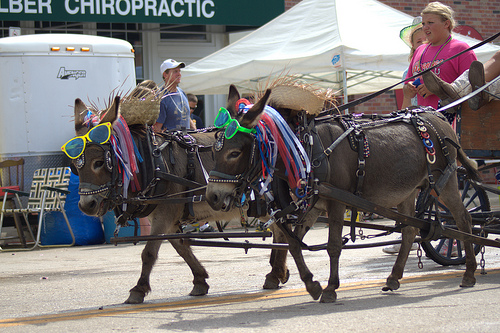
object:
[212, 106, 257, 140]
sunglasses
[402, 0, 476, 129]
woman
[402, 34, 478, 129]
shirt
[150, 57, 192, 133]
man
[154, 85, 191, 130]
shirt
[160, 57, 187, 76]
hat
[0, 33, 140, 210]
trailer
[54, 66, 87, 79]
logo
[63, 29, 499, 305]
cart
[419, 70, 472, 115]
boots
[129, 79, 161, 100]
donkey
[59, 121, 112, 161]
sunglasses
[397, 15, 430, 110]
woman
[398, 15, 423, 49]
hat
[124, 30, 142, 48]
window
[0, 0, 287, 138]
building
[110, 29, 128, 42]
window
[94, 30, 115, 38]
window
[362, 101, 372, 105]
brick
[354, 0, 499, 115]
wall